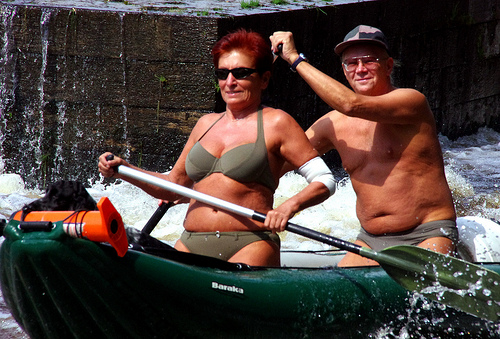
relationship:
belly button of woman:
[207, 204, 226, 216] [194, 29, 291, 262]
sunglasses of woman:
[201, 59, 266, 81] [194, 29, 291, 262]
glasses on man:
[333, 53, 388, 69] [308, 17, 462, 258]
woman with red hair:
[194, 29, 291, 262] [208, 22, 267, 69]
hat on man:
[322, 15, 398, 55] [308, 17, 462, 258]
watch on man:
[293, 49, 306, 73] [308, 17, 462, 258]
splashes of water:
[404, 270, 480, 331] [447, 110, 488, 208]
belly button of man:
[363, 206, 394, 223] [308, 17, 462, 258]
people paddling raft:
[139, 21, 473, 276] [22, 233, 395, 334]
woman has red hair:
[194, 29, 291, 262] [208, 22, 267, 69]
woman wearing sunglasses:
[194, 29, 291, 262] [201, 59, 266, 81]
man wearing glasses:
[308, 17, 462, 258] [333, 53, 388, 69]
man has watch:
[308, 17, 462, 258] [293, 49, 306, 73]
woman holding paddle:
[194, 29, 291, 262] [330, 236, 496, 329]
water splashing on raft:
[447, 110, 488, 208] [22, 233, 395, 334]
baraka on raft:
[202, 279, 247, 298] [22, 233, 395, 334]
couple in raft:
[139, 21, 473, 276] [22, 233, 395, 334]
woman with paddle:
[194, 29, 291, 262] [330, 236, 496, 329]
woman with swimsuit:
[194, 29, 291, 262] [202, 104, 272, 264]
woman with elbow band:
[194, 29, 291, 262] [299, 154, 341, 200]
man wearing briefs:
[308, 17, 462, 258] [344, 219, 451, 243]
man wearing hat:
[308, 17, 462, 258] [322, 15, 398, 55]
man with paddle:
[308, 17, 462, 258] [330, 236, 496, 329]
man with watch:
[308, 17, 462, 258] [293, 49, 306, 73]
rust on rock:
[15, 6, 46, 153] [23, 0, 176, 150]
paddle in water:
[330, 236, 496, 329] [447, 110, 488, 208]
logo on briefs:
[436, 223, 452, 238] [344, 219, 451, 243]